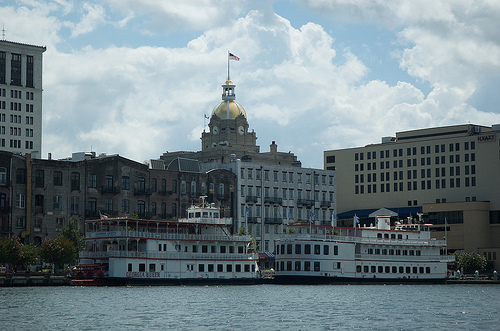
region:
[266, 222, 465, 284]
ferry boat on water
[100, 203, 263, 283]
ferry boat on water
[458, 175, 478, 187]
double window on building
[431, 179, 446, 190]
double window on building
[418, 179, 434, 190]
double window on building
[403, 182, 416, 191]
double window on building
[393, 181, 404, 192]
double window on building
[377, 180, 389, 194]
double window on building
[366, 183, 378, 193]
double window on building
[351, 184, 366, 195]
double window on building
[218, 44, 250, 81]
American flag is flying.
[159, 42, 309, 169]
American flag on building.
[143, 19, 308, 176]
Building has domed tope.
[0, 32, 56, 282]
The building is tall.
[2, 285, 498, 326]
The water is blue.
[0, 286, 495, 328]
The water is wavy.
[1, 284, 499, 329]
The water is ripply.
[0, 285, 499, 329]
The water is tranquil.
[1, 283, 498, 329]
The water is serene.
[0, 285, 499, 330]
The water is mesmerizing.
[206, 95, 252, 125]
The doom on a building.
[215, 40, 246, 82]
The American flag on top of a building.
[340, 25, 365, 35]
A patch of blue sky.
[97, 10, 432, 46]
Clouds in the sky.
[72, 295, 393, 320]
The water is blue.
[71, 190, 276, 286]
The boat is whie.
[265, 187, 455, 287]
Another white boat on the water.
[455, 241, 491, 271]
A bush on the shore.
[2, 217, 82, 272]
Trees next to the shoreline.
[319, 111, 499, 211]
A tan colored building.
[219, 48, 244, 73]
a flag on top of a building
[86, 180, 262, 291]
a river boat on the water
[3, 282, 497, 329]
a glistening river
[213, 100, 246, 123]
a gold dome on top of a building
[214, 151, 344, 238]
a concrete building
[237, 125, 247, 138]
a clock face in a building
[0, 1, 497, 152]
a blue and white cloudy sky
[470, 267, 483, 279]
a person at the water's edge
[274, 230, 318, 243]
white railing on a river boat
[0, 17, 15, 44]
an antenna on top of a building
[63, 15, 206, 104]
clear white and blue sky